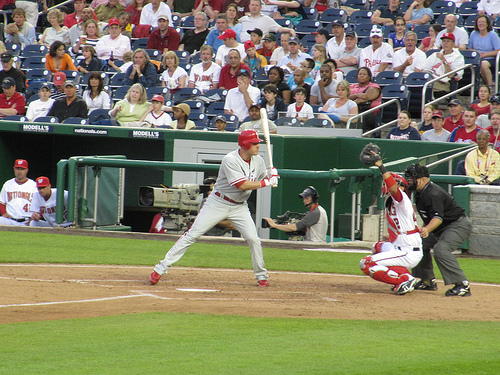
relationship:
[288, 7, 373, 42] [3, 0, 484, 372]
seats in stadium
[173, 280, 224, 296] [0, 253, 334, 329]
plate at baseball field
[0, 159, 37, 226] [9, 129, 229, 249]
man in dugout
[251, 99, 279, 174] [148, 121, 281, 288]
bat in baseball player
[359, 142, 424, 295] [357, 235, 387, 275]
catcher wearing shields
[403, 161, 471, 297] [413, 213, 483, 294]
umpire wearing pants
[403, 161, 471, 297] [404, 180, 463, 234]
umpire wearing shirt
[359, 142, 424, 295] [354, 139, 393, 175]
catcher wearing glove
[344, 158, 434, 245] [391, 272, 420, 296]
catcher wearing sneakers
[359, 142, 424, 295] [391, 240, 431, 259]
catcher wearing belt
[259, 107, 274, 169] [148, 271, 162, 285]
bat wearing shoes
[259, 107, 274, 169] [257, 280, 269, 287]
bat wearing shoe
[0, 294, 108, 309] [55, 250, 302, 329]
baseline on baseball field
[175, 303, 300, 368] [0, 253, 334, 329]
grass on baseball field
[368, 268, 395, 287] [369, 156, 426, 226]
pads on catcher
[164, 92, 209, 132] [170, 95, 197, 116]
woman wearing a hat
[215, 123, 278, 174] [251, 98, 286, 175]
baseball player up to bat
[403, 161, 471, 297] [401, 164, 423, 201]
umpire with a mask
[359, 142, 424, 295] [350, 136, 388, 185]
catcher wearing a baseball glove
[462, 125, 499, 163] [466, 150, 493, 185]
man wearing a shirt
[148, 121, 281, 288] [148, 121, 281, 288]
baseball player on a baseball player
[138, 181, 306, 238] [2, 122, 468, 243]
camera in dug out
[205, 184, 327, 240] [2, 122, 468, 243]
crew in dug out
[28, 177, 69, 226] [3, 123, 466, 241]
player in dugout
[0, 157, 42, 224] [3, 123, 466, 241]
player in dugout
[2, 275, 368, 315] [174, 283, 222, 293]
baseline around homeplate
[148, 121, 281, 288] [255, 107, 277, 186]
baseball player holding bat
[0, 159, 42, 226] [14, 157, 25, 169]
man wearing a cap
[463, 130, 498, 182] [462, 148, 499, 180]
woman wearing a shirt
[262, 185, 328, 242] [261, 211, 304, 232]
crew holding camera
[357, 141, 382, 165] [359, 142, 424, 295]
baseball glove on a catcher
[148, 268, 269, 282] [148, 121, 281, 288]
shoes on a baseball player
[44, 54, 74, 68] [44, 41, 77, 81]
shirt on a woman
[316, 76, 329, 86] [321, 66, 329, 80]
hand on a face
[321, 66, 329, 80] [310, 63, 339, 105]
face of a face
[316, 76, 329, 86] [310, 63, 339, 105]
hand of a face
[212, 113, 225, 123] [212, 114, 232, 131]
cap on a boy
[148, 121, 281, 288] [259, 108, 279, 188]
baseball player holding bat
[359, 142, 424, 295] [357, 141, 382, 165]
catcher holding baseball glove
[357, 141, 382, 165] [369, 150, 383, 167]
baseball glove on hand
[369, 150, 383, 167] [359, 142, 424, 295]
hand of catcher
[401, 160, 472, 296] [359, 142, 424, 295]
umpire behind catcher